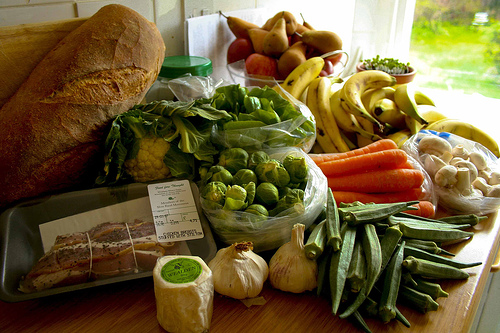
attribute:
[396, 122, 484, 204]
bag — plastic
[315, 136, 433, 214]
carrots — piled, orange, raw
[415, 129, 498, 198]
mushrooms — piled, fresh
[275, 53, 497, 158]
bananas — piled, ripe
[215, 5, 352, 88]
pears — piled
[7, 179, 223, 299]
tray — black, plastic, styrofoam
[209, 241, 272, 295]
garlic — fresh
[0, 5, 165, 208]
bread — loaf, italian, crusty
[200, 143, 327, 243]
brussel sprouts — piled, fresh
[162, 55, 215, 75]
jar — green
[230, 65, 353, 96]
bowl — clear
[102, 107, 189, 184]
cauliflower — fresh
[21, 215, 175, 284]
roll — pork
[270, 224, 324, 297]
clove — garlic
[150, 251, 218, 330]
cheese — wrapped